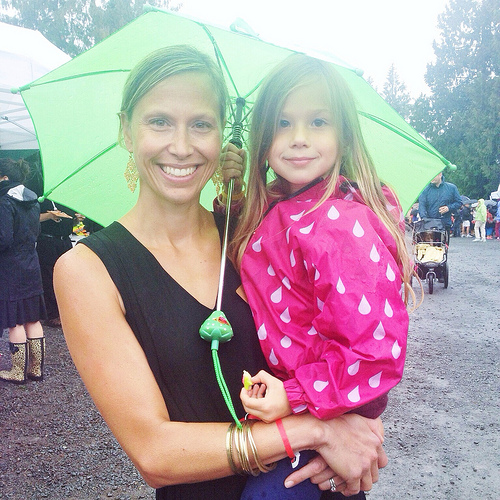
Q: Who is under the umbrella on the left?
A: A woman.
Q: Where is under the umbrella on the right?
A: A child.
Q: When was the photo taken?
A: Day time.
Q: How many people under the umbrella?
A: Two.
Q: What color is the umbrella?
A: Green.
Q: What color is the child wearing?
A: Pink.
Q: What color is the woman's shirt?
A: Black.